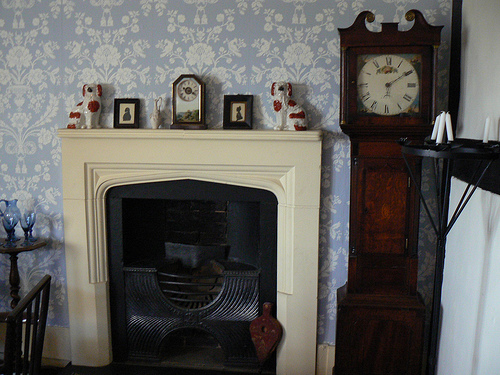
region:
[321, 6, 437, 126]
white face on clock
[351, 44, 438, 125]
roman numerals on clock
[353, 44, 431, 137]
roman numerals are black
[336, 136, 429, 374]
brown and wooden base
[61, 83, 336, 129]
figurines on top of fireplace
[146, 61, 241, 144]
clock in middle of shelf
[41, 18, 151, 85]
blue and white wallpaper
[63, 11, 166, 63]
floral pattern on wallpaper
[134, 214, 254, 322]
black and metal fireplace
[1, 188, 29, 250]
blue and glass vases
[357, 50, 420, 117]
this is a clock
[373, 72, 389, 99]
the clock is white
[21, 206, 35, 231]
this is a glass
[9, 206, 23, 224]
the glass is blue in color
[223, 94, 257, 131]
this is a picture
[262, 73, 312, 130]
this is a dog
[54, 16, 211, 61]
this is the wall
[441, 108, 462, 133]
this is a candle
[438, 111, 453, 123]
the candle is white in color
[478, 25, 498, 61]
the wall is white in color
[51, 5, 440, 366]
mantel and clock against a blue and white wall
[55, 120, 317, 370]
white mantel over dark fireplace with metal container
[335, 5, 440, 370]
grandfather clock in dark reddish wood in corner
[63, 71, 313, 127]
clock and silhouettes between ceramic dogs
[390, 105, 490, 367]
black pole supporting flared candle holder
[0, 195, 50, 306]
small stemmed blue glassware on small table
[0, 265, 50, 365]
rectangular back of wooden chair with slats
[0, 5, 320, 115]
white pattern of three flowers repeated on wallpaper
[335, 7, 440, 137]
carved curls over white clock face with black numbers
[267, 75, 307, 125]
seated white dog with brown markings looking sideways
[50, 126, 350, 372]
fireplace with mantel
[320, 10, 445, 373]
tall wooden clock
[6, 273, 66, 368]
the back of a black chair with a metal frame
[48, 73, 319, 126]
items on top of the mantel peice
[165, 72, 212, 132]
small clock sitting on the mantel piece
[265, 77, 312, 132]
one of a pair of ceramic dogs on the mantel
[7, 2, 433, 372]
wallpaper is blue and white with flowers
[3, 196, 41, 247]
light blue glass goblets and pitcher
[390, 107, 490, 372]
standing candle holder with candles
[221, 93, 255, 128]
a picture frame on the mantel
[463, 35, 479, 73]
this is the wall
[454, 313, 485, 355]
the wall is white in color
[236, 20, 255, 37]
the wall is blue in color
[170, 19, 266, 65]
the wall has drawings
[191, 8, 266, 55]
the drawings are white in color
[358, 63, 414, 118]
this is a clock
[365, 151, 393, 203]
the frame is wooden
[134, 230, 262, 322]
this is a fireplace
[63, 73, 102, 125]
this is a statue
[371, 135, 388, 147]
the wood is brown in color